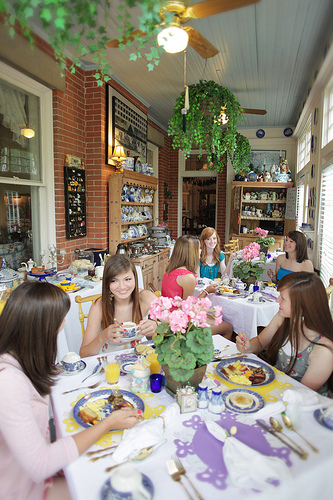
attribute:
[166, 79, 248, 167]
geranium — hanging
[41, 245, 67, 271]
candleabra — silver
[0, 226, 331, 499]
girls — together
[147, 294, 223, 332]
flowers — pink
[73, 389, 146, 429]
plate — blue rimmed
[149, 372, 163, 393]
candle holder — blue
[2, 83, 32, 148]
curtains — white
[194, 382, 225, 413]
shakers — blue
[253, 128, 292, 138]
plates — blue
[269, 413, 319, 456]
spoons — gold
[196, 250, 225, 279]
top — blue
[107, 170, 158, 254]
cabinet — wooden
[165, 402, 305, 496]
place mats — purple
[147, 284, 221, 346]
geraniums — pink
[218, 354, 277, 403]
decorations — yellow